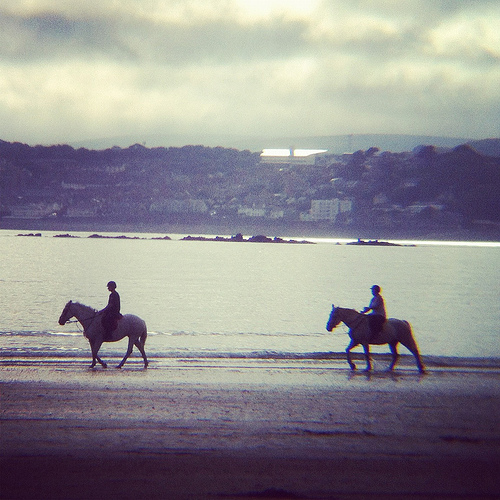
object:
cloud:
[308, 15, 419, 71]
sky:
[1, 0, 500, 150]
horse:
[60, 300, 153, 372]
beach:
[0, 352, 498, 499]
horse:
[326, 301, 426, 376]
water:
[0, 222, 500, 355]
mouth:
[59, 317, 66, 324]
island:
[335, 239, 413, 247]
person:
[99, 281, 121, 339]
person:
[364, 285, 389, 336]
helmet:
[107, 281, 117, 287]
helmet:
[370, 284, 380, 292]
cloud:
[0, 2, 141, 126]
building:
[300, 200, 354, 225]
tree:
[242, 148, 250, 156]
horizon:
[1, 125, 499, 161]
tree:
[366, 145, 380, 156]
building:
[259, 145, 332, 166]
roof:
[257, 149, 329, 157]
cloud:
[45, 75, 97, 121]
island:
[179, 235, 320, 245]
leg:
[90, 339, 109, 369]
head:
[106, 282, 116, 291]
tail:
[140, 321, 148, 351]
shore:
[0, 200, 498, 241]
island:
[86, 232, 175, 240]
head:
[370, 284, 382, 296]